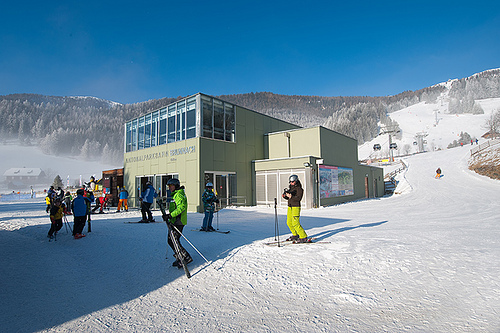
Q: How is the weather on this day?
A: It is clear.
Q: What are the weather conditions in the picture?
A: It is clear.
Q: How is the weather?
A: It is clear.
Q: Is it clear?
A: Yes, it is clear.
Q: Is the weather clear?
A: Yes, it is clear.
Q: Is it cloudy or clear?
A: It is clear.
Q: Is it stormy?
A: No, it is clear.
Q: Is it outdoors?
A: Yes, it is outdoors.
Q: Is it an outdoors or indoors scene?
A: It is outdoors.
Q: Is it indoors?
A: No, it is outdoors.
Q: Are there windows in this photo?
A: Yes, there are windows.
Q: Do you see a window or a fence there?
A: Yes, there are windows.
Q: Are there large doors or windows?
A: Yes, there are large windows.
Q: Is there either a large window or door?
A: Yes, there are large windows.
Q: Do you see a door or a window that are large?
A: Yes, the windows are large.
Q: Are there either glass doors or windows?
A: Yes, there are glass windows.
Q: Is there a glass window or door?
A: Yes, there are glass windows.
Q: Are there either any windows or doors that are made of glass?
A: Yes, the windows are made of glass.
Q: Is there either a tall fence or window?
A: Yes, there are tall windows.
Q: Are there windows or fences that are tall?
A: Yes, the windows are tall.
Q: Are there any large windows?
A: Yes, there are large windows.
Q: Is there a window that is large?
A: Yes, there are windows that are large.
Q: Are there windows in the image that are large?
A: Yes, there are windows that are large.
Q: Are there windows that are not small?
A: Yes, there are large windows.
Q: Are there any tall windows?
A: Yes, there are tall windows.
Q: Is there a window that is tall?
A: Yes, there are windows that are tall.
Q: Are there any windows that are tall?
A: Yes, there are windows that are tall.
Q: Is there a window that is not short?
A: Yes, there are tall windows.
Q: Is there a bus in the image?
A: No, there are no buses.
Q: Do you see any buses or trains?
A: No, there are no buses or trains.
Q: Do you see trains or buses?
A: No, there are no buses or trains.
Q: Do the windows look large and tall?
A: Yes, the windows are large and tall.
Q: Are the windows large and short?
A: No, the windows are large but tall.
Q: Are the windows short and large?
A: No, the windows are large but tall.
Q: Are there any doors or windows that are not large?
A: No, there are windows but they are large.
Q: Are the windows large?
A: Yes, the windows are large.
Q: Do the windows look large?
A: Yes, the windows are large.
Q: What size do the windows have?
A: The windows have large size.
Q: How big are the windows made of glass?
A: The windows are large.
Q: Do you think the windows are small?
A: No, the windows are large.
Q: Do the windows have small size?
A: No, the windows are large.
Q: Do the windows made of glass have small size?
A: No, the windows are large.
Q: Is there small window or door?
A: No, there are windows but they are large.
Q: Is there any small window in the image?
A: No, there are windows but they are large.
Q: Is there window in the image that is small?
A: No, there are windows but they are large.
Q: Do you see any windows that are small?
A: No, there are windows but they are large.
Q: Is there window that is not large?
A: No, there are windows but they are large.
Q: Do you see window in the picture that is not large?
A: No, there are windows but they are large.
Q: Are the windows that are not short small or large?
A: The windows are large.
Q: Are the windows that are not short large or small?
A: The windows are large.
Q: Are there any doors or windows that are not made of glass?
A: No, there are windows but they are made of glass.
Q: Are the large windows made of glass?
A: Yes, the windows are made of glass.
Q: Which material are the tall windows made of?
A: The windows are made of glass.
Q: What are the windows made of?
A: The windows are made of glass.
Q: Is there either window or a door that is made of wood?
A: No, there are windows but they are made of glass.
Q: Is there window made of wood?
A: No, there are windows but they are made of glass.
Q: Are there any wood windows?
A: No, there are windows but they are made of glass.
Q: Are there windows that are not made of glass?
A: No, there are windows but they are made of glass.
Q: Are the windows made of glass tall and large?
A: Yes, the windows are tall and large.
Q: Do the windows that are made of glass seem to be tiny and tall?
A: No, the windows are tall but large.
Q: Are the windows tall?
A: Yes, the windows are tall.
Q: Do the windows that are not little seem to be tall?
A: Yes, the windows are tall.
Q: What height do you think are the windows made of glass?
A: The windows are tall.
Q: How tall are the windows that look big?
A: The windows are tall.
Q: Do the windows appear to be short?
A: No, the windows are tall.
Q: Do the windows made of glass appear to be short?
A: No, the windows are tall.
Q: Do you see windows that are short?
A: No, there are windows but they are tall.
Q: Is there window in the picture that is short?
A: No, there are windows but they are tall.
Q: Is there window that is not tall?
A: No, there are windows but they are tall.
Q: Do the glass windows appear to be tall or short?
A: The windows are tall.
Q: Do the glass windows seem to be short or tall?
A: The windows are tall.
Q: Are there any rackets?
A: No, there are no rackets.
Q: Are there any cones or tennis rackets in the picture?
A: No, there are no tennis rackets or cones.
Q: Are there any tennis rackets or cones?
A: No, there are no tennis rackets or cones.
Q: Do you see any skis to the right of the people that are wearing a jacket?
A: Yes, there is a ski to the right of the people.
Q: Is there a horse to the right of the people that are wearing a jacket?
A: No, there is a ski to the right of the people.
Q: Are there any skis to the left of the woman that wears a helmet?
A: Yes, there is a ski to the left of the woman.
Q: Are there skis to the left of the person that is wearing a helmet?
A: Yes, there is a ski to the left of the woman.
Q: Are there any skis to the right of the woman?
A: No, the ski is to the left of the woman.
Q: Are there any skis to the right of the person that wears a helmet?
A: No, the ski is to the left of the woman.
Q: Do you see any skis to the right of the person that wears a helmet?
A: No, the ski is to the left of the woman.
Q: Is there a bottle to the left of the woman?
A: No, there is a ski to the left of the woman.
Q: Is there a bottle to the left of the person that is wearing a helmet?
A: No, there is a ski to the left of the woman.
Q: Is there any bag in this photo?
A: No, there are no bags.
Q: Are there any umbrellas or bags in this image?
A: No, there are no bags or umbrellas.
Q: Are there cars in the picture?
A: No, there are no cars.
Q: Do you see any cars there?
A: No, there are no cars.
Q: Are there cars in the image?
A: No, there are no cars.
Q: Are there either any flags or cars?
A: No, there are no cars or flags.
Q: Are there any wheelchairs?
A: No, there are no wheelchairs.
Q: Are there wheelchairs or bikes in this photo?
A: No, there are no wheelchairs or bikes.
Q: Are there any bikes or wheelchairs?
A: No, there are no wheelchairs or bikes.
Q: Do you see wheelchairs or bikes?
A: No, there are no wheelchairs or bikes.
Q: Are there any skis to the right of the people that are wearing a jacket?
A: Yes, there is a ski to the right of the people.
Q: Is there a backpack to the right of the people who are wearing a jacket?
A: No, there is a ski to the right of the people.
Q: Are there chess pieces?
A: No, there are no chess pieces.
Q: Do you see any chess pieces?
A: No, there are no chess pieces.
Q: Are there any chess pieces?
A: No, there are no chess pieces.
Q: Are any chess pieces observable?
A: No, there are no chess pieces.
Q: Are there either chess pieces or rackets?
A: No, there are no chess pieces or rackets.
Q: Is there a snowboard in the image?
A: No, there are no snowboards.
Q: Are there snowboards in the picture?
A: No, there are no snowboards.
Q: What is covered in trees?
A: The mountain is covered in trees.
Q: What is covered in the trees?
A: The mountain is covered in trees.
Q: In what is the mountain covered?
A: The mountain is covered in trees.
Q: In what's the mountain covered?
A: The mountain is covered in trees.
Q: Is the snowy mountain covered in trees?
A: Yes, the mountain is covered in trees.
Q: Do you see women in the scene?
A: Yes, there is a woman.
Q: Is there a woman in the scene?
A: Yes, there is a woman.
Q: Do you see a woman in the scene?
A: Yes, there is a woman.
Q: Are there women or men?
A: Yes, there is a woman.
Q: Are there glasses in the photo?
A: No, there are no glasses.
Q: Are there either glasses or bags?
A: No, there are no glasses or bags.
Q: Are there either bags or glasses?
A: No, there are no glasses or bags.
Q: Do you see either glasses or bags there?
A: No, there are no glasses or bags.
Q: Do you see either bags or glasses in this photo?
A: No, there are no glasses or bags.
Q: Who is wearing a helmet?
A: The woman is wearing a helmet.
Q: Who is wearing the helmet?
A: The woman is wearing a helmet.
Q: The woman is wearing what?
A: The woman is wearing a helmet.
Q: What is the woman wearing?
A: The woman is wearing a helmet.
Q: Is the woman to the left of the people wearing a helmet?
A: Yes, the woman is wearing a helmet.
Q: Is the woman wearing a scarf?
A: No, the woman is wearing a helmet.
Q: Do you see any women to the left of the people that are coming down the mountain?
A: Yes, there is a woman to the left of the people.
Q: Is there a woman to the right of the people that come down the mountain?
A: No, the woman is to the left of the people.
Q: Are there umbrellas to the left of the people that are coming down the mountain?
A: No, there is a woman to the left of the people.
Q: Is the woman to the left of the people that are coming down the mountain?
A: Yes, the woman is to the left of the people.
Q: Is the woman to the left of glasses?
A: No, the woman is to the left of the people.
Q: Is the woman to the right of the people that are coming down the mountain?
A: No, the woman is to the left of the people.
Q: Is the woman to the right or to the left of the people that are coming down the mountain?
A: The woman is to the left of the people.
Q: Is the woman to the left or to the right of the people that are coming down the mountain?
A: The woman is to the left of the people.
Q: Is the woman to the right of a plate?
A: No, the woman is to the right of a ski.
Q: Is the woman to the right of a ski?
A: Yes, the woman is to the right of a ski.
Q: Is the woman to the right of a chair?
A: No, the woman is to the right of a ski.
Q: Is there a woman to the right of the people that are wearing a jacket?
A: Yes, there is a woman to the right of the people.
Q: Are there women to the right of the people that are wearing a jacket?
A: Yes, there is a woman to the right of the people.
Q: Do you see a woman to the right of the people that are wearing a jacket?
A: Yes, there is a woman to the right of the people.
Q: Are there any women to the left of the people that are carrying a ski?
A: No, the woman is to the right of the people.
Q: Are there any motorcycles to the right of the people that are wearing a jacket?
A: No, there is a woman to the right of the people.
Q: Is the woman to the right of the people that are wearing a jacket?
A: Yes, the woman is to the right of the people.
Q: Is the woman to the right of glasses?
A: No, the woman is to the right of the people.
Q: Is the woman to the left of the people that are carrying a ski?
A: No, the woman is to the right of the people.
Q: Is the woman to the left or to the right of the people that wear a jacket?
A: The woman is to the right of the people.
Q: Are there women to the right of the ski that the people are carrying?
A: Yes, there is a woman to the right of the ski.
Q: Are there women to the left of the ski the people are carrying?
A: No, the woman is to the right of the ski.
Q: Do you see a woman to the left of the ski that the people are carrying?
A: No, the woman is to the right of the ski.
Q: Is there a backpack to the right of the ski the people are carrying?
A: No, there is a woman to the right of the ski.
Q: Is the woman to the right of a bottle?
A: No, the woman is to the right of a ski.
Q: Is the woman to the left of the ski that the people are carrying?
A: No, the woman is to the right of the ski.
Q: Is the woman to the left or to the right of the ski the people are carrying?
A: The woman is to the right of the ski.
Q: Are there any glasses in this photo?
A: No, there are no glasses.